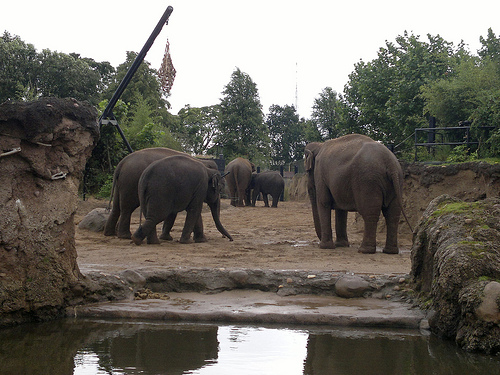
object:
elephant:
[302, 133, 409, 254]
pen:
[0, 123, 500, 372]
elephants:
[132, 154, 232, 246]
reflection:
[71, 324, 225, 375]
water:
[0, 328, 491, 373]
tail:
[389, 169, 417, 236]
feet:
[318, 190, 334, 250]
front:
[303, 137, 348, 247]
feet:
[359, 212, 380, 254]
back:
[346, 136, 405, 253]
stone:
[78, 206, 109, 232]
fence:
[410, 123, 500, 164]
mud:
[83, 239, 417, 298]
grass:
[439, 199, 476, 216]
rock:
[333, 272, 371, 298]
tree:
[214, 69, 269, 172]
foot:
[319, 239, 337, 249]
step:
[77, 294, 420, 329]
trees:
[420, 25, 500, 159]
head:
[301, 140, 319, 242]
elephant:
[251, 171, 285, 209]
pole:
[80, 5, 178, 204]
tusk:
[306, 178, 318, 218]